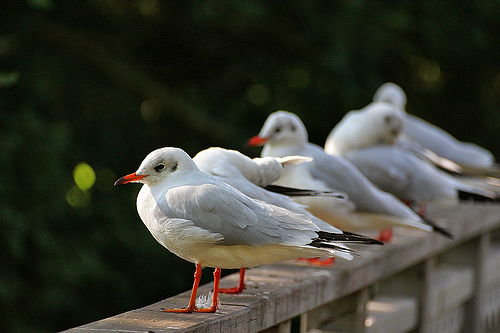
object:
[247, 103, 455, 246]
bird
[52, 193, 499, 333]
rail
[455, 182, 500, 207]
tail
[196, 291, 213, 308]
feather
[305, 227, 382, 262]
feathers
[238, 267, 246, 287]
red legs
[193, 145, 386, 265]
bird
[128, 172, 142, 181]
orange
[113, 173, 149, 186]
beak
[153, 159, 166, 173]
eye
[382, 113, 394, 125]
eye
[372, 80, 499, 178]
bird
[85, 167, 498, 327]
ledge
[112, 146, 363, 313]
bird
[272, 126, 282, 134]
eye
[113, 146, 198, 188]
white head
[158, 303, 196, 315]
orange feet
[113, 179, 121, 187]
tip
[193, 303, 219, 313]
foot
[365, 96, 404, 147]
head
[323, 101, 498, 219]
bird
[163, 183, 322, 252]
wing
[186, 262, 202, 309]
leg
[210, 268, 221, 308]
leg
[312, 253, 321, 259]
leg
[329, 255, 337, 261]
leg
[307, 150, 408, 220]
wing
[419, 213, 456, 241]
tail feather